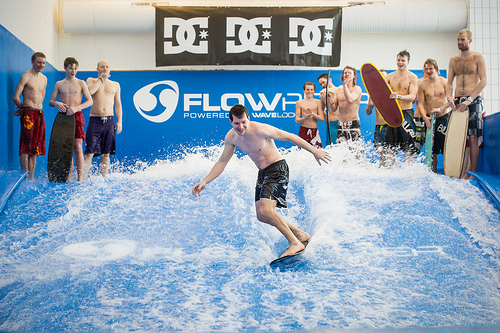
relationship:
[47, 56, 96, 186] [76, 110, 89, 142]
man wearing shorts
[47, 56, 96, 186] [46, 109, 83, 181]
man holding surfboard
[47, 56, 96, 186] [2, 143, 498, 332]
man at edge of pool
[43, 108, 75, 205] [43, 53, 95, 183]
surfboard in boys hands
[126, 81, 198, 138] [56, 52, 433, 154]
design on back wall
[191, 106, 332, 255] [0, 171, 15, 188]
man on tarp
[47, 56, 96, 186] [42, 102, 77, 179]
man holds surfboard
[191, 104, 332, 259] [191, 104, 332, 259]
man cheers man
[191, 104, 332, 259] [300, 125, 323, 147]
man wears swimming trunks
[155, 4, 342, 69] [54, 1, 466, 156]
banner on wall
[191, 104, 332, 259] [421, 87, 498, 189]
man holding surfboard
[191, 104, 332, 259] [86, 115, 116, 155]
man wears trunks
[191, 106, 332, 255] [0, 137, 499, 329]
man in wave pool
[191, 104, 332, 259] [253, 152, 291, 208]
man wears shorts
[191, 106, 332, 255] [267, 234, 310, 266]
man on surfboard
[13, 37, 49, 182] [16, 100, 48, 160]
man wears shorts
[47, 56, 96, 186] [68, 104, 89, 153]
man wears shorts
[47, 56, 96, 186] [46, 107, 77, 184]
man holds surfboard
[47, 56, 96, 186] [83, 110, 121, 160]
man wears shorts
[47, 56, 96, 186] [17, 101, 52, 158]
man in short